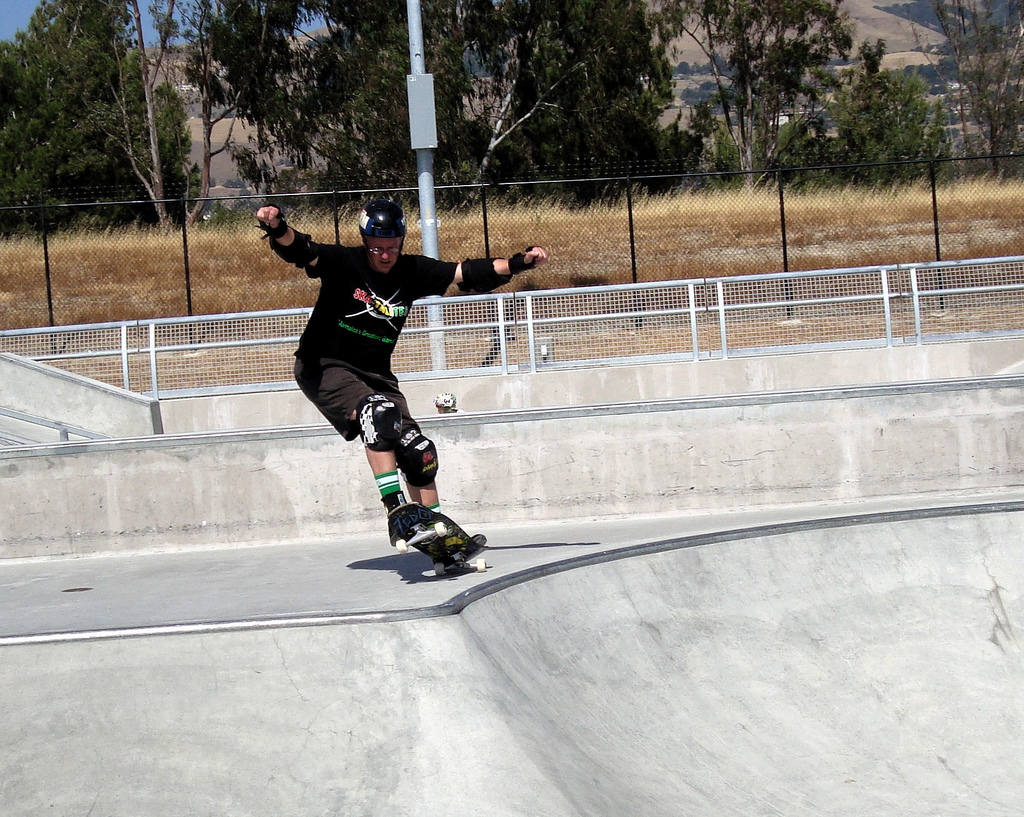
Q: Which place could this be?
A: It is a skate park.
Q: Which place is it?
A: It is a skate park.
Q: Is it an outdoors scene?
A: Yes, it is outdoors.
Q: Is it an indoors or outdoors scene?
A: It is outdoors.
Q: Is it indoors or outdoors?
A: It is outdoors.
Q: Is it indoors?
A: No, it is outdoors.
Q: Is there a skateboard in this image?
A: Yes, there is a skateboard.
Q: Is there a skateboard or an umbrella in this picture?
A: Yes, there is a skateboard.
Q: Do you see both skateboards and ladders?
A: No, there is a skateboard but no ladders.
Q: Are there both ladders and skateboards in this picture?
A: No, there is a skateboard but no ladders.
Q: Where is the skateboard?
A: The skateboard is in the skatepark.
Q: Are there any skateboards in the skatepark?
A: Yes, there is a skateboard in the skatepark.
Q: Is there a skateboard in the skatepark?
A: Yes, there is a skateboard in the skatepark.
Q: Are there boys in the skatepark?
A: No, there is a skateboard in the skatepark.